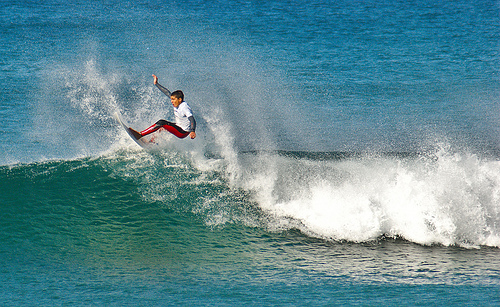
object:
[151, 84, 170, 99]
arm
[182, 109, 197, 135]
arm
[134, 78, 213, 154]
surfer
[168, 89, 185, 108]
head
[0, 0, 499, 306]
wave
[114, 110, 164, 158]
board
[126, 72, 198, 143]
surfer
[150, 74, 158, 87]
right hand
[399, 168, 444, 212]
ground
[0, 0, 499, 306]
ocean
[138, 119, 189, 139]
person's leg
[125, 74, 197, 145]
man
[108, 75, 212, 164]
surfer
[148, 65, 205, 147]
surfer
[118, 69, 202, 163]
surfer